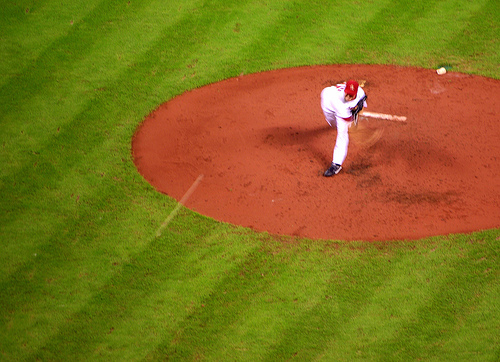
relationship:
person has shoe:
[320, 76, 367, 178] [321, 162, 344, 177]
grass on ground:
[0, 245, 499, 360] [1, 0, 493, 360]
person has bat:
[320, 76, 367, 178] [354, 106, 409, 125]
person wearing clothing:
[320, 76, 367, 178] [321, 85, 369, 167]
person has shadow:
[320, 76, 367, 178] [265, 119, 333, 169]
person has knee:
[320, 76, 367, 178] [337, 131, 348, 146]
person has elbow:
[320, 76, 367, 178] [346, 114, 356, 125]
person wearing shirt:
[320, 76, 367, 178] [320, 81, 366, 123]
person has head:
[320, 76, 367, 178] [342, 79, 359, 102]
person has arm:
[320, 76, 367, 178] [327, 94, 357, 124]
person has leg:
[320, 76, 367, 178] [335, 119, 348, 165]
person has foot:
[320, 76, 367, 178] [325, 160, 344, 177]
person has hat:
[320, 76, 367, 178] [343, 76, 361, 99]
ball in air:
[437, 66, 446, 74] [1, 2, 498, 107]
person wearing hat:
[320, 76, 367, 178] [343, 76, 361, 99]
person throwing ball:
[320, 76, 367, 178] [437, 66, 446, 74]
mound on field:
[133, 62, 497, 244] [1, 0, 493, 360]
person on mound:
[320, 76, 367, 178] [133, 62, 497, 244]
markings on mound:
[418, 75, 453, 98] [133, 62, 497, 244]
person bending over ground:
[320, 76, 367, 178] [1, 0, 493, 360]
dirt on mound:
[133, 65, 499, 243] [133, 62, 497, 244]